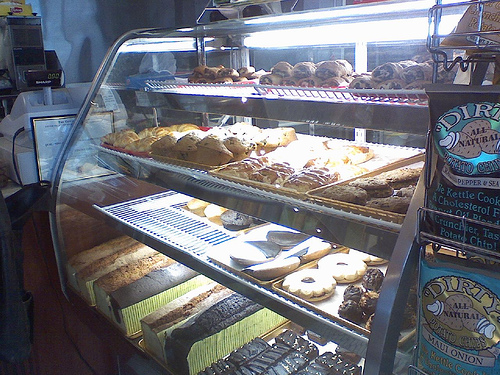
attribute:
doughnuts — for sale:
[71, 64, 451, 372]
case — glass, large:
[36, 3, 483, 364]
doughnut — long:
[288, 161, 348, 196]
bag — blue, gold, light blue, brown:
[425, 92, 499, 248]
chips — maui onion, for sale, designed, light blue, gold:
[412, 253, 497, 374]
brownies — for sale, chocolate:
[282, 332, 317, 359]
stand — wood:
[0, 172, 47, 369]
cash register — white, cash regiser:
[0, 68, 144, 185]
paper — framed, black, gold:
[28, 108, 124, 188]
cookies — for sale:
[281, 267, 338, 301]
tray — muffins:
[156, 119, 304, 173]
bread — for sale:
[164, 288, 263, 371]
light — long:
[229, 17, 469, 54]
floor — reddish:
[4, 168, 172, 374]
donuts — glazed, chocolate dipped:
[233, 235, 283, 269]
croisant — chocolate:
[267, 61, 290, 77]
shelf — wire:
[136, 68, 437, 109]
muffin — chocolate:
[195, 136, 230, 167]